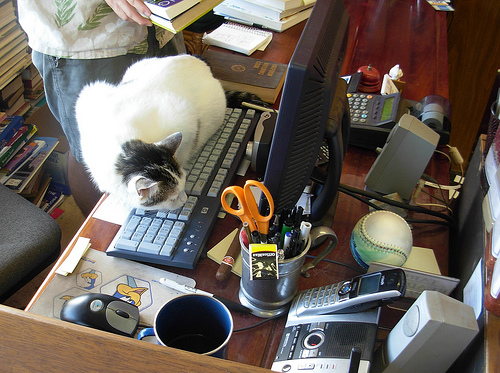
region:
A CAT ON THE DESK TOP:
[61, 47, 237, 217]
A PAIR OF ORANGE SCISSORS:
[213, 171, 284, 239]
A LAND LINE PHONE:
[260, 261, 409, 367]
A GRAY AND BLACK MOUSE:
[54, 291, 153, 336]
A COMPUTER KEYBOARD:
[99, 92, 275, 272]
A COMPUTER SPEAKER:
[359, 113, 445, 207]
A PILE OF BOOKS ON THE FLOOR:
[1, 97, 79, 229]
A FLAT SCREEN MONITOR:
[251, 1, 358, 254]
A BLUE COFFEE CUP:
[130, 287, 242, 362]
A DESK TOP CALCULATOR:
[339, 82, 464, 156]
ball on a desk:
[340, 200, 420, 282]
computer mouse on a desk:
[53, 284, 148, 349]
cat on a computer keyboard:
[63, 41, 235, 227]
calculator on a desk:
[336, 78, 406, 135]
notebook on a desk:
[196, 13, 279, 65]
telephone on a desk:
[262, 261, 412, 371]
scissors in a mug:
[211, 171, 280, 264]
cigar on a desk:
[206, 213, 246, 288]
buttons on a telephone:
[294, 278, 343, 310]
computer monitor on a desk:
[240, 0, 363, 262]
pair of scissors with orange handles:
[216, 180, 277, 240]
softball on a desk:
[348, 205, 415, 275]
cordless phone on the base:
[294, 265, 410, 315]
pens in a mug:
[243, 209, 312, 259]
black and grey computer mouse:
[57, 289, 146, 342]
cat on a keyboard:
[74, 49, 231, 216]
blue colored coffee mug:
[130, 286, 235, 363]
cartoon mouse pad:
[30, 239, 200, 349]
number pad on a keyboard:
[117, 215, 186, 257]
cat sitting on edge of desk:
[75, 47, 230, 220]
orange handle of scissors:
[220, 178, 276, 250]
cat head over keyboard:
[128, 142, 212, 241]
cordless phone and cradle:
[278, 265, 412, 330]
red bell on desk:
[349, 59, 385, 96]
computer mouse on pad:
[56, 291, 146, 334]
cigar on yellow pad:
[202, 233, 244, 289]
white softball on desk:
[347, 202, 417, 279]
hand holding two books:
[115, 2, 215, 43]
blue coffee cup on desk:
[138, 292, 233, 364]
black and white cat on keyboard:
[72, 65, 224, 212]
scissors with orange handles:
[218, 180, 283, 235]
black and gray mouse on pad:
[58, 284, 139, 333]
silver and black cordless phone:
[294, 267, 404, 372]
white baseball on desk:
[354, 200, 416, 267]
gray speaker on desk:
[400, 280, 474, 367]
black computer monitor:
[278, 8, 366, 220]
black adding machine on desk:
[341, 76, 451, 141]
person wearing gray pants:
[21, 42, 129, 149]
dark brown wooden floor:
[361, 6, 476, 60]